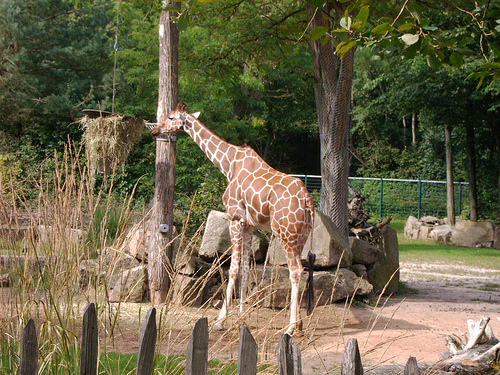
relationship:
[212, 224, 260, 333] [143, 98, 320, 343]
legs of a giraffe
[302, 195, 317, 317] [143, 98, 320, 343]
tail on giraffe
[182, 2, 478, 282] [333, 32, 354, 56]
tree with leaf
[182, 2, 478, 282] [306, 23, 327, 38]
tree with leaf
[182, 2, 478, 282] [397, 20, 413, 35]
tree with leaf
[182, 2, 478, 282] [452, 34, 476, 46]
tree with leaf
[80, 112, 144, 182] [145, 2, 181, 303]
hay bale hanging on tree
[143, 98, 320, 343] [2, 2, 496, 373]
giraffe in zoo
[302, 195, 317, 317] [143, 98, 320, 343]
tail of giraffe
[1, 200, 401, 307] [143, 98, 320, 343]
stones near giraffe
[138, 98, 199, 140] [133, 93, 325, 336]
head of giraffe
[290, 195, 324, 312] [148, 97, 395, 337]
tail of giraffe